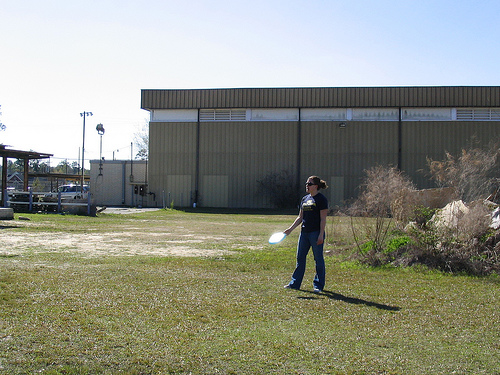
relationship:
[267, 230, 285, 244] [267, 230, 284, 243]
frisbee reflecting sunlight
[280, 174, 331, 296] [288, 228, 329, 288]
girl wearing jeans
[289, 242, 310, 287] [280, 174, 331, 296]
leg belonging to girl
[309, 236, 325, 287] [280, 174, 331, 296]
leg belonging to girl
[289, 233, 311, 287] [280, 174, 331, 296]
leg belonging to girl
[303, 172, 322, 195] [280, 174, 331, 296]
head belonging to girl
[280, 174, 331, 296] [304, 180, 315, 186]
girl wearing sunglasses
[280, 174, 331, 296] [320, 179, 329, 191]
girl wearing ponytail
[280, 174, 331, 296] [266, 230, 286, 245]
girl holding frisbee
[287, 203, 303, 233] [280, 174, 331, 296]
arm belonging to girl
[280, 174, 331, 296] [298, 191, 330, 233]
girl wearing shirt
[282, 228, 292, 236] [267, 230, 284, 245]
hand holding frisbee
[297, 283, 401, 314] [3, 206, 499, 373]
shadow casted on ground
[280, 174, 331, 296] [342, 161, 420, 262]
girl standing in front of bush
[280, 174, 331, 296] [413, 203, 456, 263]
girl standing in front of bush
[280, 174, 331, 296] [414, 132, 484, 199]
girl standing in front of bush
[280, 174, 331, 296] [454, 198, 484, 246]
girl standing in front of bush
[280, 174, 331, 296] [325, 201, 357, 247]
girl standing in front of bush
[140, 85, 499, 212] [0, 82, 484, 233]
building standing in background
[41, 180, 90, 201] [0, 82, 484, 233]
van parked in background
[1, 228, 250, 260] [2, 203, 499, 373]
spot appearing in field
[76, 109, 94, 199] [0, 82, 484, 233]
light pole standing in background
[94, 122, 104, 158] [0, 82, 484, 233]
light pole standing in background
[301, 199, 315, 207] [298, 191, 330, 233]
logo printed on shirt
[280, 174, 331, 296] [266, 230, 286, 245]
girl playing with frisbee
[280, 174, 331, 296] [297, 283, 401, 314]
girl casting shadow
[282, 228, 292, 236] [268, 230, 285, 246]
hand holding frisbee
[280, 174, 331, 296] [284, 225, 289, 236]
girl has hand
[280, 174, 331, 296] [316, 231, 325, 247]
girl has hand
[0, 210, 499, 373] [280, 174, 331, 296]
grassy area near girl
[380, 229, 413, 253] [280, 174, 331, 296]
bush near girl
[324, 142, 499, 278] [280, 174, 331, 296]
bush near girl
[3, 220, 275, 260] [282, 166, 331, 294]
dirt area near player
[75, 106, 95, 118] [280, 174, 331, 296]
lights near girl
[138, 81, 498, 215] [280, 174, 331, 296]
building behind girl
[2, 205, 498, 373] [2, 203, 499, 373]
grass in field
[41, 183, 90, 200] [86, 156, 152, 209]
van parked in front of building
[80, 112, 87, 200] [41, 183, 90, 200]
light pole by van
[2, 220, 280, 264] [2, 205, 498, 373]
dirt patch in grass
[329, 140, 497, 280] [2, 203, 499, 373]
weeds growing in field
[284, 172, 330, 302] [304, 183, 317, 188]
girl wearing sunglasses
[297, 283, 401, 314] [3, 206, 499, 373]
shadow on ground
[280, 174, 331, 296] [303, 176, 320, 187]
girl wearing sunglasses